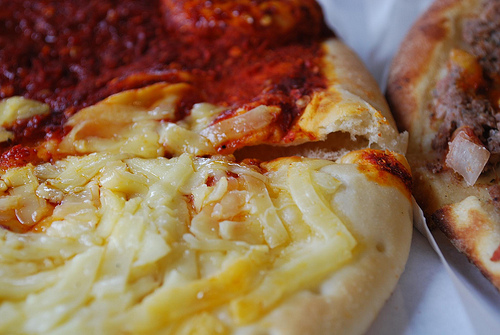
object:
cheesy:
[0, 153, 292, 331]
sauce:
[0, 10, 271, 84]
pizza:
[0, 0, 384, 335]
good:
[267, 168, 419, 335]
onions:
[0, 161, 273, 282]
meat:
[435, 79, 490, 121]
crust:
[300, 163, 412, 334]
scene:
[0, 4, 500, 335]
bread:
[393, 21, 451, 118]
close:
[277, 165, 332, 227]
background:
[0, 0, 500, 125]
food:
[0, 90, 404, 335]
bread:
[298, 89, 381, 139]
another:
[370, 0, 500, 335]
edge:
[368, 77, 414, 188]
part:
[179, 45, 389, 151]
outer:
[270, 157, 418, 335]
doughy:
[276, 88, 398, 140]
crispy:
[330, 142, 420, 176]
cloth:
[375, 199, 500, 335]